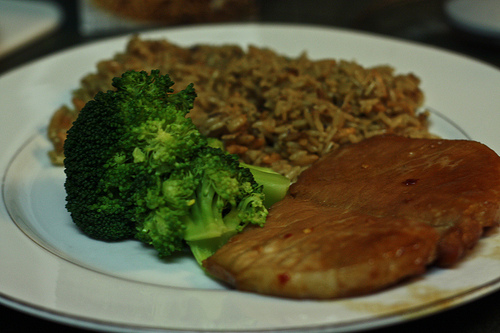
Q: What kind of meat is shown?
A: Pork.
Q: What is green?
A: Broccoli.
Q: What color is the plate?
A: White.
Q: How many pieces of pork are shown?
A: 1.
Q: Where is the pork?
A: Right side.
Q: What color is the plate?
A: White.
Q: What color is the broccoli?
A: Green.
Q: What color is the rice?
A: Brown.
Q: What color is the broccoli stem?
A: Green.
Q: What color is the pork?
A: Brown.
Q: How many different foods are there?
A: 3.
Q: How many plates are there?
A: One.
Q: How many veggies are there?
A: One.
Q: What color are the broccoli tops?
A: Green.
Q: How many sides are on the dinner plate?
A: 2.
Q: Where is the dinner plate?
A: On the table.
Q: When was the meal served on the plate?
A: 7:00 PM Sunday.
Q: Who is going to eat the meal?
A: The father.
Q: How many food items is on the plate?
A: 3.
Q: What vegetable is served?
A: Broccoli.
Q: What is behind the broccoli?
A: Brown rice.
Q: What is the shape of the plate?
A: Round.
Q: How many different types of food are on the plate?
A: Three.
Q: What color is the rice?
A: Brown.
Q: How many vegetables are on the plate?
A: One.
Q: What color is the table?
A: Black.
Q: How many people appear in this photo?
A: Zero.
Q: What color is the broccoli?
A: Green.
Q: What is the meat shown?
A: Pork chop.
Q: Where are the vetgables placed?
A: Beside the pork chop.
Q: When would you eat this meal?
A: Dinner.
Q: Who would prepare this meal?
A: The cook.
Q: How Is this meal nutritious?
A: It includes basic food groups.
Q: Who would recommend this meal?
A: A nutritionist.